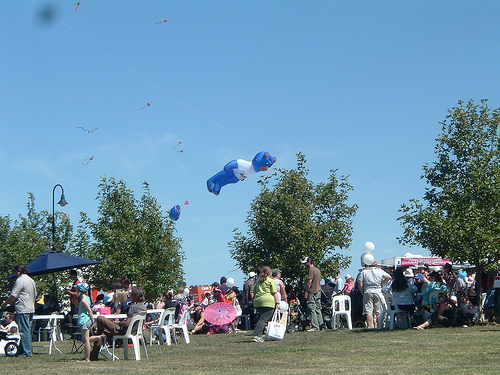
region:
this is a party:
[13, 71, 492, 361]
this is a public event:
[152, 67, 489, 337]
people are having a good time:
[196, 253, 368, 350]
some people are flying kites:
[37, 78, 302, 233]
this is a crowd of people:
[6, 242, 196, 353]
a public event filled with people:
[221, 245, 497, 346]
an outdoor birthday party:
[17, 242, 493, 308]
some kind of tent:
[376, 238, 456, 264]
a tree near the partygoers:
[235, 155, 351, 275]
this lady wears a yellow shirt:
[248, 263, 281, 345]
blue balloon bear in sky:
[205, 150, 275, 194]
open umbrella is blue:
[19, 247, 96, 276]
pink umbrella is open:
[203, 301, 234, 322]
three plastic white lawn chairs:
[110, 301, 191, 358]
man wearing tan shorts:
[351, 260, 389, 329]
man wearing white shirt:
[352, 261, 391, 334]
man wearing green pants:
[299, 258, 325, 330]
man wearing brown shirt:
[301, 259, 325, 329]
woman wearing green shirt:
[248, 268, 281, 340]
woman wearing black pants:
[249, 267, 283, 350]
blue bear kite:
[198, 140, 278, 197]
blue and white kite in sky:
[197, 139, 277, 206]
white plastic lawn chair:
[109, 305, 154, 368]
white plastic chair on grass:
[322, 288, 356, 338]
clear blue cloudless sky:
[224, 12, 411, 113]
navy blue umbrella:
[7, 246, 97, 276]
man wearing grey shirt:
[9, 264, 37, 317]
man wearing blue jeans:
[9, 265, 44, 368]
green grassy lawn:
[296, 332, 471, 367]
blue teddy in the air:
[195, 135, 282, 205]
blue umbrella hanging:
[27, 242, 90, 272]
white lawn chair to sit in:
[111, 315, 163, 369]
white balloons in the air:
[355, 234, 378, 266]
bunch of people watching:
[396, 265, 486, 329]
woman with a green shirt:
[250, 264, 301, 344]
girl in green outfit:
[68, 286, 98, 341]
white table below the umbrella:
[33, 313, 68, 356]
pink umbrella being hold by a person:
[200, 300, 242, 325]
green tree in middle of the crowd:
[247, 165, 352, 271]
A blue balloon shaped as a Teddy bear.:
[205, 149, 275, 196]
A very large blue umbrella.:
[20, 250, 99, 276]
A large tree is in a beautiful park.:
[226, 148, 358, 287]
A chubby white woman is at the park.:
[245, 266, 277, 342]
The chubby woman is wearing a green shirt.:
[249, 275, 276, 307]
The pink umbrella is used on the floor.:
[201, 300, 238, 325]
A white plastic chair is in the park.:
[111, 312, 148, 360]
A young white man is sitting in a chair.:
[87, 285, 147, 362]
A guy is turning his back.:
[0, 262, 37, 356]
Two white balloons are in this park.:
[361, 240, 374, 266]